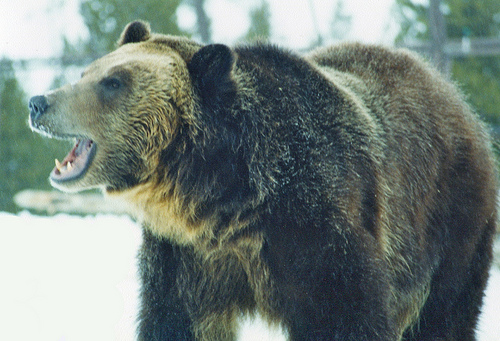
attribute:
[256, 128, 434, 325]
bear — brown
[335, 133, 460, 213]
bear — brown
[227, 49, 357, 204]
bear — brown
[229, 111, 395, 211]
bear — brown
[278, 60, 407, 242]
bear — brown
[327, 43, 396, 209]
bear — brown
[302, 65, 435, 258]
bear — brown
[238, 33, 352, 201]
bear — brown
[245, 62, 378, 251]
bear — brown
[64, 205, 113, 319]
snow — white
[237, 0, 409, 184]
bear — brown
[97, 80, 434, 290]
bear — brown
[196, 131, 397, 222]
bear — brown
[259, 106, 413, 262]
bear — brown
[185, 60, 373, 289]
bear — brown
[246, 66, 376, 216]
bear — brown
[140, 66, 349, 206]
bear — brown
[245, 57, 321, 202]
bear — brown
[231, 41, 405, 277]
bear — brown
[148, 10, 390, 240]
bear — brown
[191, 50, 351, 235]
bear — brown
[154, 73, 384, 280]
bear — brown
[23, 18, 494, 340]
bear — brown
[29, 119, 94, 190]
mouth — open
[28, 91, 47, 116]
nose — black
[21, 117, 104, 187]
mouth — open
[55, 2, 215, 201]
trees — green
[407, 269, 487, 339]
leg — back